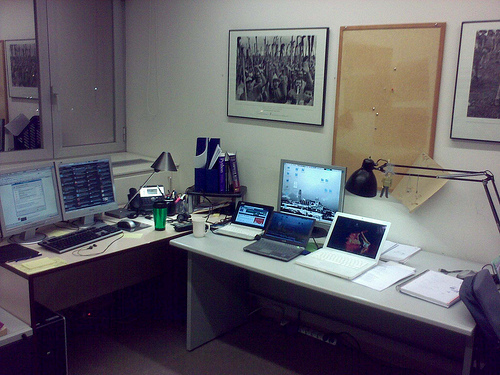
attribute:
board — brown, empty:
[330, 21, 446, 192]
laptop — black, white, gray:
[244, 208, 316, 264]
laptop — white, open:
[296, 212, 393, 283]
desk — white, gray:
[169, 211, 495, 369]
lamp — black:
[345, 157, 498, 227]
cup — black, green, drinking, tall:
[151, 199, 167, 232]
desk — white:
[1, 204, 189, 370]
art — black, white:
[221, 26, 329, 128]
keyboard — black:
[39, 221, 124, 252]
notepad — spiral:
[395, 268, 464, 314]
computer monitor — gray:
[275, 158, 345, 230]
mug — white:
[189, 213, 210, 235]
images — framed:
[218, 18, 497, 147]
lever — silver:
[49, 87, 58, 110]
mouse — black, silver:
[118, 219, 139, 230]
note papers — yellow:
[23, 255, 61, 275]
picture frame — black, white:
[223, 24, 329, 127]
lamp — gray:
[104, 151, 177, 220]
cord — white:
[276, 314, 343, 349]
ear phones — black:
[70, 230, 126, 259]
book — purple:
[226, 149, 242, 191]